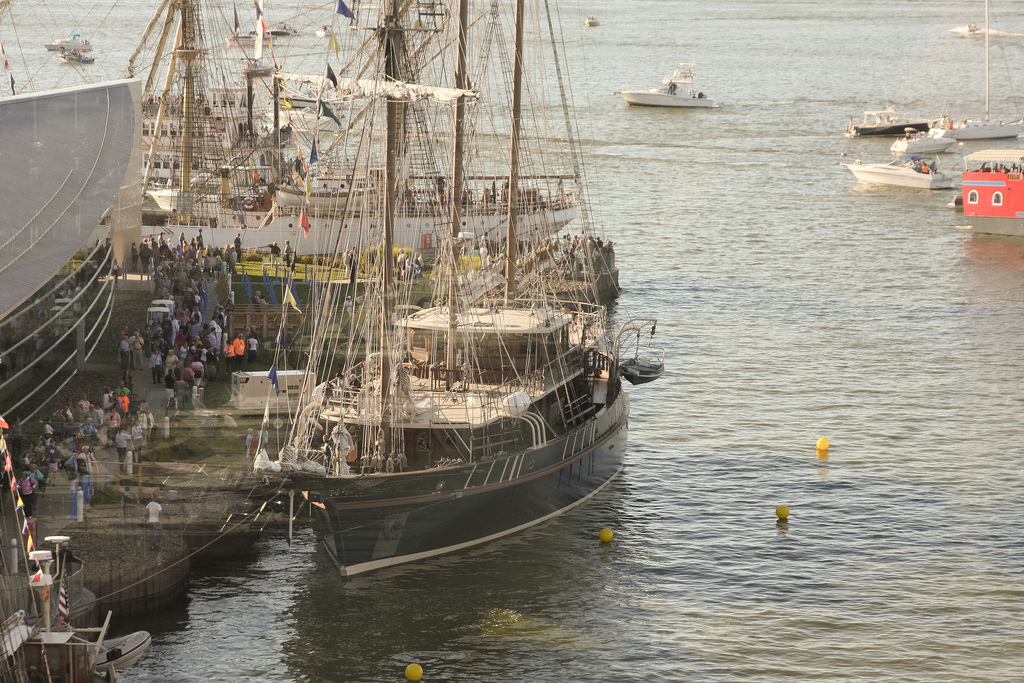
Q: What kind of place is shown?
A: It is a harbor.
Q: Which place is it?
A: It is a harbor.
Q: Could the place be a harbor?
A: Yes, it is a harbor.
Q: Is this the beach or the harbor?
A: It is the harbor.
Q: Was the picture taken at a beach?
A: No, the picture was taken in a harbor.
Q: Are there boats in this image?
A: Yes, there is a boat.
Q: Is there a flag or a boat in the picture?
A: Yes, there is a boat.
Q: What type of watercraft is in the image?
A: The watercraft is a boat.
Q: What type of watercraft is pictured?
A: The watercraft is a boat.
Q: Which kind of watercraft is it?
A: The watercraft is a boat.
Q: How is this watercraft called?
A: This is a boat.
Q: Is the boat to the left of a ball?
A: Yes, the boat is to the left of a ball.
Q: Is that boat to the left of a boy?
A: No, the boat is to the left of a ball.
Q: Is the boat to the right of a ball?
A: No, the boat is to the left of a ball.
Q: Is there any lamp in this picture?
A: No, there are no lamps.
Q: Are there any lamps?
A: No, there are no lamps.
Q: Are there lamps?
A: No, there are no lamps.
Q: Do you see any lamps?
A: No, there are no lamps.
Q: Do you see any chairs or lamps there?
A: No, there are no lamps or chairs.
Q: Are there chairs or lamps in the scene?
A: No, there are no lamps or chairs.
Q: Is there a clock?
A: No, there are no clocks.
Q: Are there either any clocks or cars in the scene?
A: No, there are no clocks or cars.